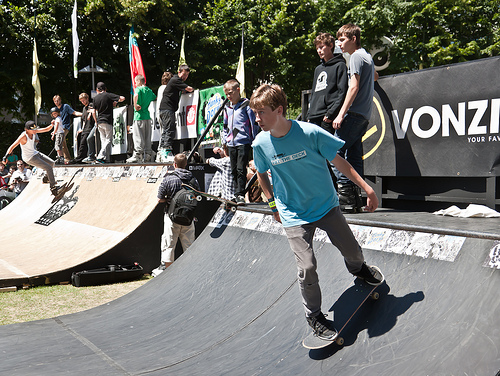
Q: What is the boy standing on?
A: Skateboard.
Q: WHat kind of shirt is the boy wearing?
A: T-shirt.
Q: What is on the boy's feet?
A: Tennis shoes.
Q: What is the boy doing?
A: Skateboarding.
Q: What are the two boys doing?
A: Skateboarding.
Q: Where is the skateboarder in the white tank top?
A: On the left.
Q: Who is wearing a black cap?
A: Skateboarder on the left.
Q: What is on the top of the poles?
A: Flags.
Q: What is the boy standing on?
A: Skateboard.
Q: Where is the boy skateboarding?
A: A skateboard park.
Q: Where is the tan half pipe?
A: On the left.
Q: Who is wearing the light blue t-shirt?
A: Boy skateboarding.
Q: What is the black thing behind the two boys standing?
A: Advertisement banner.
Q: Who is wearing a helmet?
A: No one is wearing a helmet.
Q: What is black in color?
A: The ramp.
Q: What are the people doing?
A: Skating.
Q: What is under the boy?
A: Skateboard.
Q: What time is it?
A: Afternoon.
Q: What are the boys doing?
A: Skateboarding.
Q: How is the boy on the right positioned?
A: Downward.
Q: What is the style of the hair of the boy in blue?
A: Traditional.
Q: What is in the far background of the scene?
A: Trees.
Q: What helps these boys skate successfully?
A: Fitness.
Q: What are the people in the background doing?
A: Waiting around.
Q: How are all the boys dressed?
A: Casually.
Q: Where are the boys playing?
A: Skate park.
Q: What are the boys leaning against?
A: Sponsor ads.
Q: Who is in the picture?
A: Boys.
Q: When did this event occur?
A: During the day.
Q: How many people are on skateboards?
A: 2.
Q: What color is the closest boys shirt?
A: Blue.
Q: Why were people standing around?
A: To watch.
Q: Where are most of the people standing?
A: On a skateboard ramp.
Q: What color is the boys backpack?
A: Black.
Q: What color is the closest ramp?
A: Black.